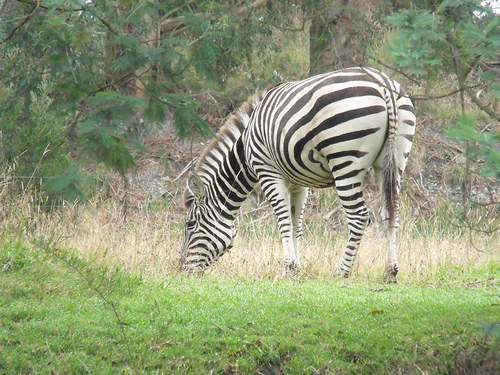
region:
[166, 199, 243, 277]
head of a zebra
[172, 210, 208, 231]
eye of a zebra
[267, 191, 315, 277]
leg of a zebra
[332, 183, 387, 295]
leg of a zebra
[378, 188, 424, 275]
leg of a zebra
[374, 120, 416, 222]
tail of a zebra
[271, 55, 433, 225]
body of a zebra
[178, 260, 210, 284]
mouth of a zebra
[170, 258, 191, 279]
nose of a zebra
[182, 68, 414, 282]
the zebra is grazing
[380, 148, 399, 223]
a black and white tail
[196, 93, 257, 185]
neck hair is standing up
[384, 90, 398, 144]
the tail is striped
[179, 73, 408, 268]
a zebra has black and white stripes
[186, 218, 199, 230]
zebras eyes are open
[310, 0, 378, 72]
a large truck of a tree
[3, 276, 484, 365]
lively green grass on the ground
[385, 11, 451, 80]
green leaves on the branches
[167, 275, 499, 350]
ground of green grass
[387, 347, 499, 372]
patch of brown grass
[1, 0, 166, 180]
leaves flowing down from branches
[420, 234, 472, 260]
over grown brown grass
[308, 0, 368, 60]
trunk of tree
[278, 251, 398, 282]
hooves of zebra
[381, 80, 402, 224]
zebra tail with long fur at the end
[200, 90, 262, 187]
zebra mane growing down neck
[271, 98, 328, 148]
black and white stripes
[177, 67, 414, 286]
zebra grazing grass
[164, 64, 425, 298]
A zebra on the grass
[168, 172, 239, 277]
The face of a zebra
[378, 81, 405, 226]
The tail of a zebra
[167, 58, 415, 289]
A zebra eating grass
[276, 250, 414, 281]
The feet of a zebra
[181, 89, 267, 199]
The mane of a zebra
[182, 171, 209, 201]
The ear of a zebra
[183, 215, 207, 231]
The eye of a zebra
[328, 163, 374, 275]
The leg of a zebra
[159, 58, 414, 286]
A zebra on the grass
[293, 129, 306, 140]
the zebra has a white stripe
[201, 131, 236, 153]
the hair is standing up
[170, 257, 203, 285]
the zebra is eating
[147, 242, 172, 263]
the grass is dead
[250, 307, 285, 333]
the grass is green in color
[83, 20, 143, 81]
the branches have leaves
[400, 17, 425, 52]
the leaves are green in color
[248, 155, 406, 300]
the zebra is standing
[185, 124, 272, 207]
the neck is pointed downward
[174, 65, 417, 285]
black and white zebra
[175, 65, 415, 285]
zebra grazing on grass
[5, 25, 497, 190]
A forest of trees in the background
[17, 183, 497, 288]
The tall dry grass